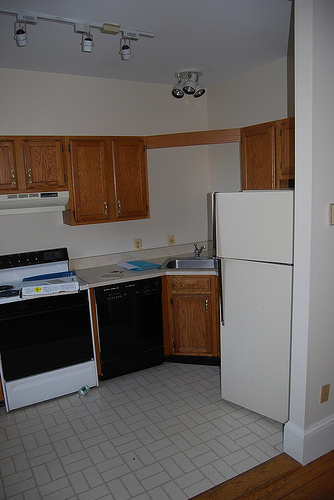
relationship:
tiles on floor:
[0, 360, 284, 499] [0, 360, 334, 499]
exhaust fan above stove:
[0, 189, 68, 216] [0, 247, 91, 305]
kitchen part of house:
[0, 0, 295, 499] [0, 0, 333, 500]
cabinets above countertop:
[2, 117, 295, 227] [67, 239, 213, 288]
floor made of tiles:
[0, 360, 334, 499] [0, 360, 284, 499]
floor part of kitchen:
[0, 360, 334, 499] [0, 0, 295, 499]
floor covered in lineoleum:
[0, 360, 334, 499] [0, 360, 284, 499]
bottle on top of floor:
[74, 384, 91, 401] [0, 360, 334, 499]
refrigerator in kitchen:
[204, 184, 297, 434] [0, 0, 295, 499]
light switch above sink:
[166, 233, 176, 246] [157, 256, 217, 271]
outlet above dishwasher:
[132, 236, 143, 253] [92, 273, 165, 378]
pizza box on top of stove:
[19, 269, 81, 301] [0, 247, 91, 305]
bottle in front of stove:
[74, 384, 91, 401] [0, 247, 99, 412]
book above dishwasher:
[126, 258, 162, 272] [92, 273, 165, 378]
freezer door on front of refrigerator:
[210, 188, 294, 265] [204, 184, 297, 434]